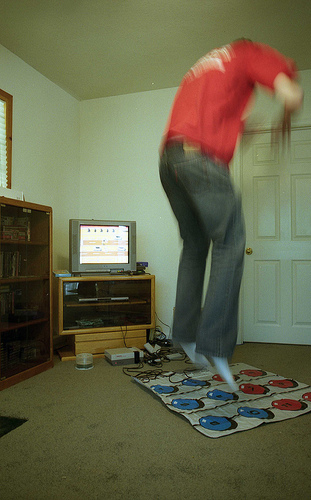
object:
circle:
[199, 414, 233, 432]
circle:
[236, 404, 269, 418]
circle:
[171, 395, 200, 411]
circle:
[206, 386, 235, 402]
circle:
[149, 382, 175, 397]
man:
[153, 36, 304, 395]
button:
[272, 395, 304, 413]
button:
[239, 382, 268, 398]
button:
[269, 377, 295, 388]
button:
[242, 368, 265, 378]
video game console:
[105, 345, 144, 364]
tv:
[69, 218, 136, 273]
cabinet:
[56, 270, 155, 360]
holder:
[76, 352, 94, 370]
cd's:
[77, 358, 92, 366]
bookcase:
[0, 193, 55, 392]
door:
[235, 119, 310, 348]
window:
[0, 87, 14, 188]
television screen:
[78, 225, 127, 263]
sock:
[205, 359, 241, 394]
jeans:
[163, 143, 247, 358]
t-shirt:
[173, 40, 296, 146]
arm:
[250, 40, 303, 110]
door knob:
[245, 245, 255, 258]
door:
[62, 283, 151, 328]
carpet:
[36, 397, 155, 499]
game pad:
[130, 360, 310, 442]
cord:
[125, 351, 179, 384]